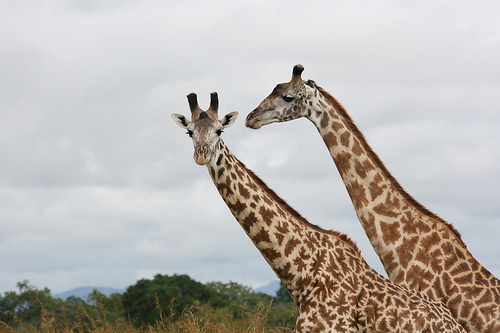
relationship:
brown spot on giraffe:
[243, 209, 260, 231] [173, 90, 460, 332]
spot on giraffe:
[249, 227, 275, 250] [173, 90, 460, 332]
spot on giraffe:
[237, 180, 247, 195] [173, 90, 460, 332]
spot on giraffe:
[256, 203, 275, 224] [173, 90, 460, 332]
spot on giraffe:
[277, 217, 289, 235] [173, 90, 460, 332]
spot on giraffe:
[268, 227, 283, 243] [173, 90, 460, 332]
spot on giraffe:
[281, 230, 298, 261] [173, 90, 460, 332]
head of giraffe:
[151, 100, 268, 177] [148, 103, 402, 323]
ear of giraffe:
[170, 111, 190, 128] [173, 90, 460, 332]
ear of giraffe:
[219, 110, 237, 131] [173, 90, 460, 332]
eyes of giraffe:
[184, 127, 224, 140] [152, 89, 451, 331]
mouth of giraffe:
[241, 106, 280, 128] [244, 63, 499, 330]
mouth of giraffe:
[190, 140, 212, 162] [173, 90, 460, 332]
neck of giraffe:
[205, 145, 358, 293] [173, 90, 460, 332]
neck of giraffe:
[312, 92, 462, 279] [244, 63, 499, 330]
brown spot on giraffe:
[398, 241, 417, 262] [244, 63, 499, 330]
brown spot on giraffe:
[374, 197, 396, 214] [244, 63, 499, 330]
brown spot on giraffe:
[380, 223, 401, 239] [244, 63, 499, 330]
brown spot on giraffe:
[455, 270, 473, 283] [244, 63, 499, 330]